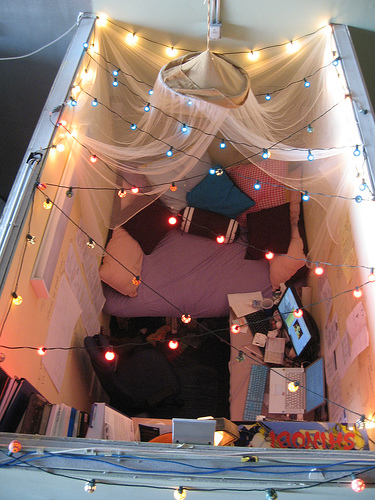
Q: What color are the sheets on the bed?
A: Purple.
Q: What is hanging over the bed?
A: Net.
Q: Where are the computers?
A: The desk.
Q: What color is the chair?
A: Black.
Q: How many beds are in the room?
A: One.